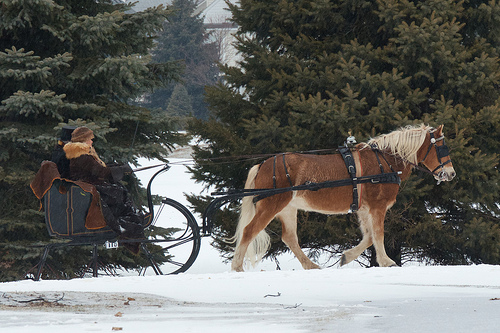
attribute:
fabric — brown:
[33, 163, 104, 228]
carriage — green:
[15, 112, 233, 289]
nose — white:
[440, 162, 465, 184]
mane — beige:
[370, 118, 426, 168]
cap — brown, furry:
[69, 123, 93, 140]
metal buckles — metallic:
[343, 150, 353, 158]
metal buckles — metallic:
[347, 165, 355, 172]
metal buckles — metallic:
[349, 182, 358, 191]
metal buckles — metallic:
[350, 202, 358, 209]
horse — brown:
[234, 122, 457, 269]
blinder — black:
[431, 140, 453, 166]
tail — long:
[222, 165, 270, 270]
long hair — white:
[358, 118, 428, 165]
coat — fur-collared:
[53, 140, 133, 213]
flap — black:
[432, 136, 451, 160]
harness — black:
[234, 141, 403, 214]